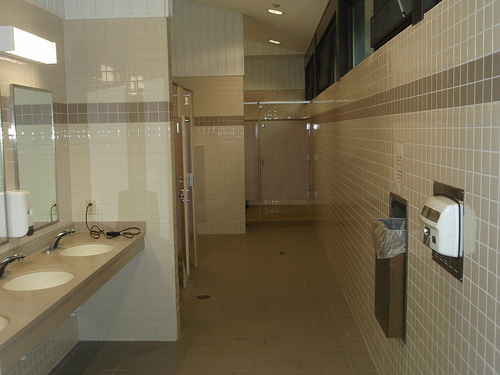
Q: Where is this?
A: This is at the bathroom.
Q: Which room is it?
A: It is a bathroom.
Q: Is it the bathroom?
A: Yes, it is the bathroom.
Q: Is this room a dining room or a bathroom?
A: It is a bathroom.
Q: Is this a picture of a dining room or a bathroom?
A: It is showing a bathroom.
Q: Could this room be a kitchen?
A: No, it is a bathroom.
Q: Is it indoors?
A: Yes, it is indoors.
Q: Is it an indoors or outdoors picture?
A: It is indoors.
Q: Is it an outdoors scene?
A: No, it is indoors.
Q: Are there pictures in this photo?
A: No, there are no pictures.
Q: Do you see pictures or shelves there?
A: No, there are no pictures or shelves.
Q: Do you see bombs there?
A: No, there are no bombs.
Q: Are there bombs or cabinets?
A: No, there are no bombs or cabinets.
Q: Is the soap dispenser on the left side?
A: Yes, the soap dispenser is on the left of the image.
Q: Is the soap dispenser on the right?
A: No, the soap dispenser is on the left of the image.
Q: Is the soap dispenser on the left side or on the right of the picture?
A: The soap dispenser is on the left of the image.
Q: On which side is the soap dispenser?
A: The soap dispenser is on the left of the image.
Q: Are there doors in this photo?
A: Yes, there is a door.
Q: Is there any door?
A: Yes, there is a door.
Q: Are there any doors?
A: Yes, there is a door.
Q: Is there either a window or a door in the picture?
A: Yes, there is a door.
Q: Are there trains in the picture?
A: No, there are no trains.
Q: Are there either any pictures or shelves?
A: No, there are no shelves or pictures.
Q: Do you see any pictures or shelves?
A: No, there are no shelves or pictures.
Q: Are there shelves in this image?
A: No, there are no shelves.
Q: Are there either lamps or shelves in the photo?
A: No, there are no shelves or lamps.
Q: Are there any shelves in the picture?
A: No, there are no shelves.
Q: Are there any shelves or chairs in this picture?
A: No, there are no shelves or chairs.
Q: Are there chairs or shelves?
A: No, there are no shelves or chairs.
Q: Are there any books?
A: No, there are no books.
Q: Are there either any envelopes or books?
A: No, there are no books or envelopes.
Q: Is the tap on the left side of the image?
A: Yes, the tap is on the left of the image.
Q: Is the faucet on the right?
A: No, the faucet is on the left of the image.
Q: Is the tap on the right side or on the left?
A: The tap is on the left of the image.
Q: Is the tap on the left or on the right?
A: The tap is on the left of the image.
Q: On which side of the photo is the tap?
A: The tap is on the left of the image.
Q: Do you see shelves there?
A: No, there are no shelves.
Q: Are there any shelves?
A: No, there are no shelves.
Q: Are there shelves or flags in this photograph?
A: No, there are no shelves or flags.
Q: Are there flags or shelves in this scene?
A: No, there are no shelves or flags.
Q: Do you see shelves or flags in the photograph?
A: No, there are no shelves or flags.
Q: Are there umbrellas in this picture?
A: No, there are no umbrellas.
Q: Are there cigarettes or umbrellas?
A: No, there are no umbrellas or cigarettes.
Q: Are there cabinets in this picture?
A: No, there are no cabinets.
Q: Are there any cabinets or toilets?
A: No, there are no cabinets or toilets.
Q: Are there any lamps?
A: No, there are no lamps.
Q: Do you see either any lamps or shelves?
A: No, there are no lamps or shelves.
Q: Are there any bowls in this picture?
A: No, there are no bowls.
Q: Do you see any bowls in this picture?
A: No, there are no bowls.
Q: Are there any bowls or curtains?
A: No, there are no bowls or curtains.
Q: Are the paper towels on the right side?
A: No, the paper towels are on the left of the image.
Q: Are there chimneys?
A: No, there are no chimneys.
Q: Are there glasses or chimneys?
A: No, there are no chimneys or glasses.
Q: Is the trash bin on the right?
A: Yes, the trash bin is on the right of the image.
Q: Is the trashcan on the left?
A: No, the trashcan is on the right of the image.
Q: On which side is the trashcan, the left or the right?
A: The trashcan is on the right of the image.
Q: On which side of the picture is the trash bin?
A: The trash bin is on the right of the image.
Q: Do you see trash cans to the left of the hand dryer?
A: Yes, there is a trash can to the left of the hand dryer.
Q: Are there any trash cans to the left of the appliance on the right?
A: Yes, there is a trash can to the left of the hand dryer.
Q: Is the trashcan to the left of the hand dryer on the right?
A: Yes, the trashcan is to the left of the hand dryer.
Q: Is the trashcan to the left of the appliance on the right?
A: Yes, the trashcan is to the left of the hand dryer.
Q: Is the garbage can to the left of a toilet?
A: No, the garbage can is to the left of the hand dryer.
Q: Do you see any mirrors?
A: Yes, there is a mirror.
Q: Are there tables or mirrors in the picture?
A: Yes, there is a mirror.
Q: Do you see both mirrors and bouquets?
A: No, there is a mirror but no bouquets.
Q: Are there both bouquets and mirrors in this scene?
A: No, there is a mirror but no bouquets.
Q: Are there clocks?
A: No, there are no clocks.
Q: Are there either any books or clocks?
A: No, there are no clocks or books.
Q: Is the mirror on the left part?
A: Yes, the mirror is on the left of the image.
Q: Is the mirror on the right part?
A: No, the mirror is on the left of the image.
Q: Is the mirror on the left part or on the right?
A: The mirror is on the left of the image.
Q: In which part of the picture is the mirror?
A: The mirror is on the left of the image.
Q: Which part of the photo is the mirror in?
A: The mirror is on the left of the image.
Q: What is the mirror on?
A: The mirror is on the wall.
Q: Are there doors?
A: Yes, there is a door.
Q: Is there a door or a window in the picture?
A: Yes, there is a door.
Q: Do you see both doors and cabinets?
A: No, there is a door but no cabinets.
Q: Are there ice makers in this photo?
A: No, there are no ice makers.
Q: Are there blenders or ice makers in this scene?
A: No, there are no ice makers or blenders.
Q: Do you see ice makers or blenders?
A: No, there are no ice makers or blenders.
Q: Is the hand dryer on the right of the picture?
A: Yes, the hand dryer is on the right of the image.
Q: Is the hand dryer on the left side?
A: No, the hand dryer is on the right of the image.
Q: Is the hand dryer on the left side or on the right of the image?
A: The hand dryer is on the right of the image.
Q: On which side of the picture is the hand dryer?
A: The hand dryer is on the right of the image.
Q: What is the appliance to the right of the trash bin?
A: The appliance is a hand dryer.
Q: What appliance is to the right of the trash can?
A: The appliance is a hand dryer.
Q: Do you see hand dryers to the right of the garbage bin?
A: Yes, there is a hand dryer to the right of the garbage bin.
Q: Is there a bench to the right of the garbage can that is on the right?
A: No, there is a hand dryer to the right of the garbage can.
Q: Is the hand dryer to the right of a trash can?
A: Yes, the hand dryer is to the right of a trash can.